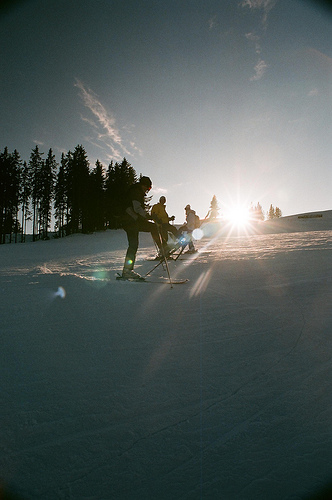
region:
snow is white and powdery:
[49, 343, 306, 495]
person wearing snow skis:
[101, 163, 202, 297]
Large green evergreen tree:
[61, 141, 94, 238]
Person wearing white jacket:
[173, 202, 209, 256]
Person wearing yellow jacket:
[147, 194, 184, 256]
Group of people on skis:
[100, 162, 209, 306]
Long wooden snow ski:
[104, 274, 201, 287]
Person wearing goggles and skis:
[109, 171, 160, 288]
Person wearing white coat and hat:
[173, 197, 205, 256]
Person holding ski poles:
[147, 191, 177, 263]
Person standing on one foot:
[90, 165, 179, 300]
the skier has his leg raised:
[114, 217, 178, 259]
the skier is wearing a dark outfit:
[118, 188, 160, 256]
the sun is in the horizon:
[222, 198, 253, 235]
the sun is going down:
[214, 196, 255, 232]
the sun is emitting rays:
[203, 189, 271, 273]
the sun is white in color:
[208, 191, 257, 242]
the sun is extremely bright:
[221, 195, 249, 230]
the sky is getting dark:
[2, 1, 331, 226]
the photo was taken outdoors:
[2, 1, 329, 498]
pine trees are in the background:
[3, 138, 158, 240]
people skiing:
[115, 159, 234, 331]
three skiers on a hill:
[39, 173, 305, 339]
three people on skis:
[63, 154, 331, 307]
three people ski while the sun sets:
[84, 155, 292, 294]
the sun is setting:
[207, 188, 330, 246]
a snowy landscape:
[12, 211, 328, 488]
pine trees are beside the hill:
[5, 132, 251, 240]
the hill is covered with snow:
[34, 182, 326, 416]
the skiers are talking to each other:
[78, 142, 276, 328]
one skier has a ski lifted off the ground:
[96, 163, 205, 315]